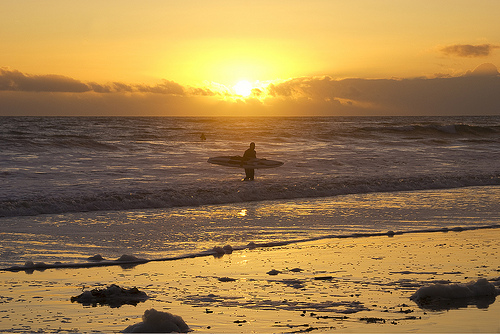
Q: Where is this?
A: This is at the beach.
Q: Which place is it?
A: It is a beach.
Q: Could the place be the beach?
A: Yes, it is the beach.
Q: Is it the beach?
A: Yes, it is the beach.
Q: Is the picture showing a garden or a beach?
A: It is showing a beach.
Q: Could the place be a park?
A: No, it is a beach.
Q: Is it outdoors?
A: Yes, it is outdoors.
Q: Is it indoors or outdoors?
A: It is outdoors.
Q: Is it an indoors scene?
A: No, it is outdoors.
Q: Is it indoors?
A: No, it is outdoors.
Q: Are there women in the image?
A: No, there are no women.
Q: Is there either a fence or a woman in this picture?
A: No, there are no women or fences.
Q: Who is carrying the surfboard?
A: The man is carrying the surfboard.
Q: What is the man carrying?
A: The man is carrying a surfboard.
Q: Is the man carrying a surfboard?
A: Yes, the man is carrying a surfboard.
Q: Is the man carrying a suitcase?
A: No, the man is carrying a surfboard.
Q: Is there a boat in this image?
A: No, there are no boats.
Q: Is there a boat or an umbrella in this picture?
A: No, there are no boats or umbrellas.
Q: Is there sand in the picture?
A: Yes, there is sand.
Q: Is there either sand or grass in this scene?
A: Yes, there is sand.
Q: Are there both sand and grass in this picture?
A: No, there is sand but no grass.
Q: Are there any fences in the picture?
A: No, there are no fences.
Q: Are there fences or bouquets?
A: No, there are no fences or bouquets.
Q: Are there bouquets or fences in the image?
A: No, there are no fences or bouquets.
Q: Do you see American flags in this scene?
A: No, there are no American flags.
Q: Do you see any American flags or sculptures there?
A: No, there are no American flags or sculptures.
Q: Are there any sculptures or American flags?
A: No, there are no American flags or sculptures.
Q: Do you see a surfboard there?
A: Yes, there is a surfboard.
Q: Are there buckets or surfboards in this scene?
A: Yes, there is a surfboard.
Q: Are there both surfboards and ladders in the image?
A: No, there is a surfboard but no ladders.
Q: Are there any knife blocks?
A: No, there are no knife blocks.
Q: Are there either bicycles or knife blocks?
A: No, there are no knife blocks or bicycles.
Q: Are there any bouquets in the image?
A: No, there are no bouquets.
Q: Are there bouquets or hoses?
A: No, there are no bouquets or hoses.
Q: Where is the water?
A: The water is on the sand.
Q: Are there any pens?
A: No, there are no pens.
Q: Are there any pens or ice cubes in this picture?
A: No, there are no pens or ice cubes.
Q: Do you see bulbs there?
A: No, there are no bulbs.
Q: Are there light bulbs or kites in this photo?
A: No, there are no light bulbs or kites.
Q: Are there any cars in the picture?
A: No, there are no cars.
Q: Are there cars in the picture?
A: No, there are no cars.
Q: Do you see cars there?
A: No, there are no cars.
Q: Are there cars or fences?
A: No, there are no cars or fences.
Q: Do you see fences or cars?
A: No, there are no cars or fences.